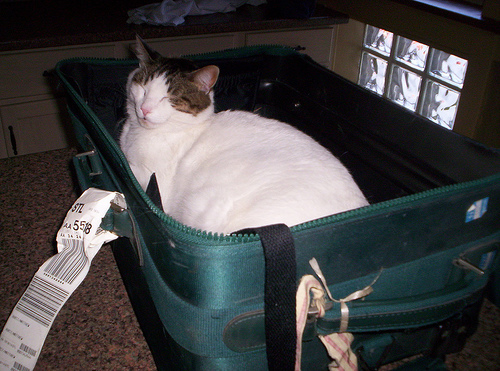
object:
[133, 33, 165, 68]
ear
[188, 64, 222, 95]
ear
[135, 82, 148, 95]
eye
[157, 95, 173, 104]
eye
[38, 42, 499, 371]
suitcase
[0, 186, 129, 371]
tag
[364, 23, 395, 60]
window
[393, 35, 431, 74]
window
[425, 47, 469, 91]
window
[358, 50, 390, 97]
window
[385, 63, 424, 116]
window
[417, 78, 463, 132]
window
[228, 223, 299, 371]
rope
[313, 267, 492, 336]
handle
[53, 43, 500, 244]
zipper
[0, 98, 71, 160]
cupboard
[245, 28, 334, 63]
drawer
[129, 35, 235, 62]
drawer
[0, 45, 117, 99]
drawer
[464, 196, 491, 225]
tag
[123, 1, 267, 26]
rag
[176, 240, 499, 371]
green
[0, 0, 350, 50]
counter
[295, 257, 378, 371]
strap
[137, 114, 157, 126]
mouth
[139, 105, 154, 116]
nose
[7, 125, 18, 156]
handle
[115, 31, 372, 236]
cat